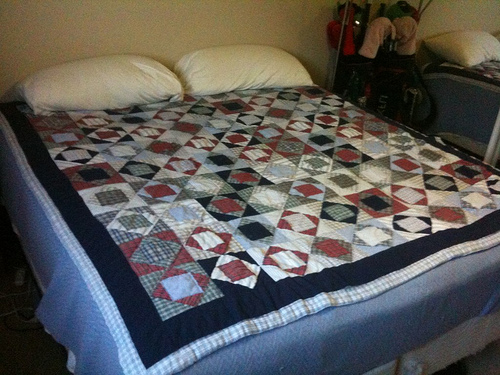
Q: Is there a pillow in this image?
A: Yes, there is a pillow.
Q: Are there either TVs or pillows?
A: Yes, there is a pillow.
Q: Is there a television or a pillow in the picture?
A: Yes, there is a pillow.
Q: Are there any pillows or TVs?
A: Yes, there is a pillow.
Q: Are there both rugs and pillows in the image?
A: No, there is a pillow but no rugs.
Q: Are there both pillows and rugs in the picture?
A: No, there is a pillow but no rugs.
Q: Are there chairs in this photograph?
A: No, there are no chairs.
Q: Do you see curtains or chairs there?
A: No, there are no chairs or curtains.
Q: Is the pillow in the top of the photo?
A: Yes, the pillow is in the top of the image.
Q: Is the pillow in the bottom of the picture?
A: No, the pillow is in the top of the image.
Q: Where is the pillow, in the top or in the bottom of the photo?
A: The pillow is in the top of the image.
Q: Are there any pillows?
A: Yes, there is a pillow.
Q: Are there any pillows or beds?
A: Yes, there is a pillow.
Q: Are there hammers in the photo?
A: No, there are no hammers.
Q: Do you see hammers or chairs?
A: No, there are no hammers or chairs.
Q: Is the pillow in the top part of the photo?
A: Yes, the pillow is in the top of the image.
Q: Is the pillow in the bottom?
A: No, the pillow is in the top of the image.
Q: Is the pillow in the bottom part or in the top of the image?
A: The pillow is in the top of the image.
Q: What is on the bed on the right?
A: The pillow is on the bed.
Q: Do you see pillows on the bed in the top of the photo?
A: Yes, there is a pillow on the bed.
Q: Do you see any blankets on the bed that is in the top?
A: No, there is a pillow on the bed.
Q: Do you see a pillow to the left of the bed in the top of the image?
A: Yes, there is a pillow to the left of the bed.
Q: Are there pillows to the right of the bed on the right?
A: No, the pillow is to the left of the bed.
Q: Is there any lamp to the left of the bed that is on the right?
A: No, there is a pillow to the left of the bed.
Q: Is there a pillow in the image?
A: Yes, there is a pillow.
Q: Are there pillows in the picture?
A: Yes, there is a pillow.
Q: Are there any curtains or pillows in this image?
A: Yes, there is a pillow.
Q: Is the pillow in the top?
A: Yes, the pillow is in the top of the image.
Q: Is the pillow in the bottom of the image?
A: No, the pillow is in the top of the image.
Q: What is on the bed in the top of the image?
A: The pillow is on the bed.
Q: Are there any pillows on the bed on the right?
A: Yes, there is a pillow on the bed.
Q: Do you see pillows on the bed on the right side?
A: Yes, there is a pillow on the bed.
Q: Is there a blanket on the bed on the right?
A: No, there is a pillow on the bed.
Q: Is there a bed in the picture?
A: Yes, there is a bed.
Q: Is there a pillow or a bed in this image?
A: Yes, there is a bed.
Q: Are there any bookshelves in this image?
A: No, there are no bookshelves.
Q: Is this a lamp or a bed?
A: This is a bed.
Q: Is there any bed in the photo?
A: Yes, there is a bed.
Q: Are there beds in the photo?
A: Yes, there is a bed.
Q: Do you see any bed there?
A: Yes, there is a bed.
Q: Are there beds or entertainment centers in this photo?
A: Yes, there is a bed.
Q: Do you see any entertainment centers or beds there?
A: Yes, there is a bed.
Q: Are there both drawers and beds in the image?
A: No, there is a bed but no drawers.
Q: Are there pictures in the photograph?
A: No, there are no pictures.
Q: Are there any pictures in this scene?
A: No, there are no pictures.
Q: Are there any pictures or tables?
A: No, there are no pictures or tables.